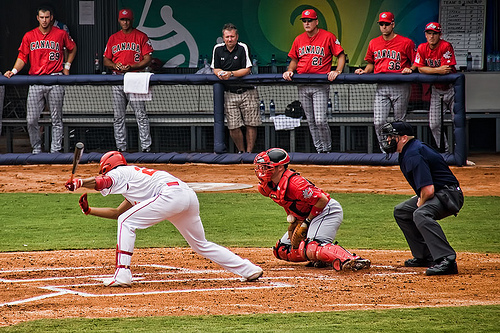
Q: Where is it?
A: This is at the field.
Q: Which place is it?
A: It is a field.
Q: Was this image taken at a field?
A: Yes, it was taken in a field.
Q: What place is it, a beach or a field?
A: It is a field.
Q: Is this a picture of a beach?
A: No, the picture is showing a field.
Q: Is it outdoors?
A: Yes, it is outdoors.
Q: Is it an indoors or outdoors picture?
A: It is outdoors.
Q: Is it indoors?
A: No, it is outdoors.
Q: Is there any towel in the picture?
A: Yes, there is a towel.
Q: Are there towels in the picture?
A: Yes, there is a towel.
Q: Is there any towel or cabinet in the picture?
A: Yes, there is a towel.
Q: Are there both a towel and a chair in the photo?
A: No, there is a towel but no chairs.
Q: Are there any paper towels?
A: No, there are no paper towels.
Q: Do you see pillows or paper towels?
A: No, there are no paper towels or pillows.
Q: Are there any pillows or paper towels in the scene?
A: No, there are no paper towels or pillows.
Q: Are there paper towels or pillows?
A: No, there are no paper towels or pillows.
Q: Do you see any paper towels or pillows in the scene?
A: No, there are no paper towels or pillows.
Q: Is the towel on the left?
A: Yes, the towel is on the left of the image.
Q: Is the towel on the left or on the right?
A: The towel is on the left of the image.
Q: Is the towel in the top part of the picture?
A: Yes, the towel is in the top of the image.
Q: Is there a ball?
A: No, there are no balls.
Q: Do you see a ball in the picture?
A: No, there are no balls.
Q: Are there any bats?
A: Yes, there is a bat.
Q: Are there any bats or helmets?
A: Yes, there is a bat.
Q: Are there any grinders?
A: No, there are no grinders.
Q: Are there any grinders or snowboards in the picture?
A: No, there are no grinders or snowboards.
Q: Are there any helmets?
A: Yes, there is a helmet.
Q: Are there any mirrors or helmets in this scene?
A: Yes, there is a helmet.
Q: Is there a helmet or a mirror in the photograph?
A: Yes, there is a helmet.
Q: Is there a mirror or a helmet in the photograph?
A: Yes, there is a helmet.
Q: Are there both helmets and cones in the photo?
A: No, there is a helmet but no cones.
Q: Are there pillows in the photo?
A: No, there are no pillows.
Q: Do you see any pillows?
A: No, there are no pillows.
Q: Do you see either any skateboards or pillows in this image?
A: No, there are no pillows or skateboards.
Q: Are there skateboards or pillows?
A: No, there are no pillows or skateboards.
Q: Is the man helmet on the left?
A: Yes, the helmet is on the left of the image.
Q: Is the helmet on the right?
A: No, the helmet is on the left of the image.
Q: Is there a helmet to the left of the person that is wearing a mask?
A: Yes, there is a helmet to the left of the person.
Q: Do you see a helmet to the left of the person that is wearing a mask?
A: Yes, there is a helmet to the left of the person.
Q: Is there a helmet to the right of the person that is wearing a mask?
A: No, the helmet is to the left of the person.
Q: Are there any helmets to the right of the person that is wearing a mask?
A: No, the helmet is to the left of the person.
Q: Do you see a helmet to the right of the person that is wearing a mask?
A: No, the helmet is to the left of the person.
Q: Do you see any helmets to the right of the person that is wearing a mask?
A: No, the helmet is to the left of the person.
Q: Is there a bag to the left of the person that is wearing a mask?
A: No, there is a helmet to the left of the person.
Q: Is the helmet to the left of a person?
A: Yes, the helmet is to the left of a person.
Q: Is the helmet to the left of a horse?
A: No, the helmet is to the left of a person.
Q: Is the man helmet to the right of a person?
A: No, the helmet is to the left of a person.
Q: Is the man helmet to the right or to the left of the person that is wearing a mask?
A: The helmet is to the left of the person.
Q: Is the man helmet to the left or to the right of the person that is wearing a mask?
A: The helmet is to the left of the person.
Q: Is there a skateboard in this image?
A: No, there are no skateboards.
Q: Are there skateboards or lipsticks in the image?
A: No, there are no skateboards or lipsticks.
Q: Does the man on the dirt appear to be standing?
A: Yes, the man is standing.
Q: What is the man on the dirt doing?
A: The man is standing.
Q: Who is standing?
A: The man is standing.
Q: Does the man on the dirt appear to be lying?
A: No, the man is standing.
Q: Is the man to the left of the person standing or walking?
A: The man is standing.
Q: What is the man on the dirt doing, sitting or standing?
A: The man is standing.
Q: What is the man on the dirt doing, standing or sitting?
A: The man is standing.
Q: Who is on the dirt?
A: The man is on the dirt.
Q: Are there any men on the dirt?
A: Yes, there is a man on the dirt.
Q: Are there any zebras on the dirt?
A: No, there is a man on the dirt.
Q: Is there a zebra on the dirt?
A: No, there is a man on the dirt.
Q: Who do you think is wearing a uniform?
A: The man is wearing a uniform.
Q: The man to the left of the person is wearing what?
A: The man is wearing a uniform.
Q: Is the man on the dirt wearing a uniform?
A: Yes, the man is wearing a uniform.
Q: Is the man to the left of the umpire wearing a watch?
A: No, the man is wearing a uniform.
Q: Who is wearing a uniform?
A: The man is wearing a uniform.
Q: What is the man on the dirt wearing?
A: The man is wearing a uniform.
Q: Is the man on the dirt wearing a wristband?
A: No, the man is wearing a uniform.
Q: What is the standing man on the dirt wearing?
A: The man is wearing a uniform.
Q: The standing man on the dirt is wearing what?
A: The man is wearing a uniform.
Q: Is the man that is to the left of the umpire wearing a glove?
A: No, the man is wearing a uniform.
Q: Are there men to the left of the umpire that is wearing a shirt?
A: Yes, there is a man to the left of the umpire.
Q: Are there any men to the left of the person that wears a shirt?
A: Yes, there is a man to the left of the umpire.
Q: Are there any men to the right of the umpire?
A: No, the man is to the left of the umpire.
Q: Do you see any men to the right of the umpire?
A: No, the man is to the left of the umpire.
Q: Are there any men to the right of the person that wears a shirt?
A: No, the man is to the left of the umpire.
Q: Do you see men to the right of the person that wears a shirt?
A: No, the man is to the left of the umpire.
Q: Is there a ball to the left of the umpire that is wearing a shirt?
A: No, there is a man to the left of the umpire.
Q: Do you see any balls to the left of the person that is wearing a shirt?
A: No, there is a man to the left of the umpire.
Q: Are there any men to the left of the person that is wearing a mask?
A: Yes, there is a man to the left of the person.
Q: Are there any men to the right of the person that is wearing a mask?
A: No, the man is to the left of the person.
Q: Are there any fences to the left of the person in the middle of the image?
A: No, there is a man to the left of the person.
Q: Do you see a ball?
A: No, there are no balls.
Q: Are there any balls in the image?
A: No, there are no balls.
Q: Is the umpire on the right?
A: Yes, the umpire is on the right of the image.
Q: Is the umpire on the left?
A: No, the umpire is on the right of the image.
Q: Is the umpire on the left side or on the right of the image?
A: The umpire is on the right of the image.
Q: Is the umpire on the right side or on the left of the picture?
A: The umpire is on the right of the image.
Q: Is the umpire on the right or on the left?
A: The umpire is on the right of the image.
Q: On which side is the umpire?
A: The umpire is on the right of the image.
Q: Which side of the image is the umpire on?
A: The umpire is on the right of the image.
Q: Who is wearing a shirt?
A: The umpire is wearing a shirt.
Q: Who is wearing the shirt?
A: The umpire is wearing a shirt.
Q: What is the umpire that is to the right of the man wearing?
A: The umpire is wearing a shirt.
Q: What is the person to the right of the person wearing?
A: The umpire is wearing a shirt.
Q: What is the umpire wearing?
A: The umpire is wearing a shirt.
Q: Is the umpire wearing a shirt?
A: Yes, the umpire is wearing a shirt.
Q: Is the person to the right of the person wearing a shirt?
A: Yes, the umpire is wearing a shirt.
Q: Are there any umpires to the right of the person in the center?
A: Yes, there is an umpire to the right of the person.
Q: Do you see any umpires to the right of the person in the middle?
A: Yes, there is an umpire to the right of the person.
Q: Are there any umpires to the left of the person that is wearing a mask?
A: No, the umpire is to the right of the person.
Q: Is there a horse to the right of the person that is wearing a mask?
A: No, there is an umpire to the right of the person.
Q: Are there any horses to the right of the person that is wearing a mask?
A: No, there is an umpire to the right of the person.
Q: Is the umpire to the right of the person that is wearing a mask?
A: Yes, the umpire is to the right of the person.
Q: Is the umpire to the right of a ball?
A: No, the umpire is to the right of the person.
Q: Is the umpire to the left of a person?
A: No, the umpire is to the right of a person.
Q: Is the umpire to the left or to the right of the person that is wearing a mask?
A: The umpire is to the right of the person.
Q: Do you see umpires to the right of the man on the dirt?
A: Yes, there is an umpire to the right of the man.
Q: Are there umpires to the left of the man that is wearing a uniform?
A: No, the umpire is to the right of the man.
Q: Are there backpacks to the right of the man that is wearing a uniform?
A: No, there is an umpire to the right of the man.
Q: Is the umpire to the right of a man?
A: Yes, the umpire is to the right of a man.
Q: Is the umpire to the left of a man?
A: No, the umpire is to the right of a man.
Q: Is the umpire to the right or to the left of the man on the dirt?
A: The umpire is to the right of the man.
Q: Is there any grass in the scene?
A: Yes, there is grass.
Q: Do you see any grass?
A: Yes, there is grass.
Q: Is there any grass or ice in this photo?
A: Yes, there is grass.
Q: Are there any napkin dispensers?
A: No, there are no napkin dispensers.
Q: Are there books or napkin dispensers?
A: No, there are no napkin dispensers or books.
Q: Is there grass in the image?
A: Yes, there is grass.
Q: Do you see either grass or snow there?
A: Yes, there is grass.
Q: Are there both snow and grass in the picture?
A: No, there is grass but no snow.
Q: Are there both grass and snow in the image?
A: No, there is grass but no snow.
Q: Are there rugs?
A: No, there are no rugs.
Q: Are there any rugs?
A: No, there are no rugs.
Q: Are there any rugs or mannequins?
A: No, there are no rugs or mannequins.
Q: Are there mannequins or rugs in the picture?
A: No, there are no rugs or mannequins.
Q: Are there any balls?
A: No, there are no balls.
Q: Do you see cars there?
A: No, there are no cars.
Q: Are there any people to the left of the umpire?
A: Yes, there is a person to the left of the umpire.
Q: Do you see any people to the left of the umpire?
A: Yes, there is a person to the left of the umpire.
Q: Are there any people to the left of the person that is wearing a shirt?
A: Yes, there is a person to the left of the umpire.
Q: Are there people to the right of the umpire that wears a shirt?
A: No, the person is to the left of the umpire.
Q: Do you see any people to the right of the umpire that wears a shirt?
A: No, the person is to the left of the umpire.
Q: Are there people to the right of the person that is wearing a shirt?
A: No, the person is to the left of the umpire.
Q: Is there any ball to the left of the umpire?
A: No, there is a person to the left of the umpire.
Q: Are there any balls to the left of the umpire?
A: No, there is a person to the left of the umpire.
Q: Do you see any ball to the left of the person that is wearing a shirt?
A: No, there is a person to the left of the umpire.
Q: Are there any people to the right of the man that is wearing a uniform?
A: Yes, there is a person to the right of the man.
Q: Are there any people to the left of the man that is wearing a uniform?
A: No, the person is to the right of the man.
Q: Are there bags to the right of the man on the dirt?
A: No, there is a person to the right of the man.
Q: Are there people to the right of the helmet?
A: Yes, there is a person to the right of the helmet.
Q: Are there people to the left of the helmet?
A: No, the person is to the right of the helmet.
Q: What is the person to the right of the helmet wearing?
A: The person is wearing a mask.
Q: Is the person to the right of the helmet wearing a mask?
A: Yes, the person is wearing a mask.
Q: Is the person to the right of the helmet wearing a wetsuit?
A: No, the person is wearing a mask.